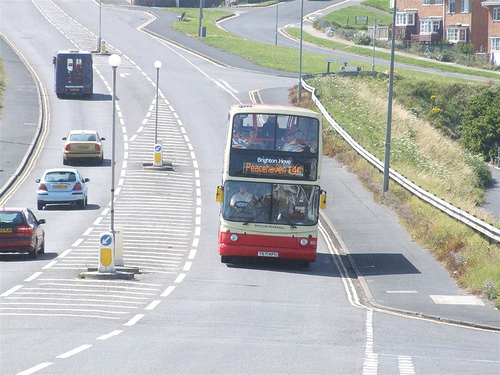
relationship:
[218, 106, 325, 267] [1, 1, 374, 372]
bus in road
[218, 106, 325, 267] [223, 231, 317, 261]
bus has bumper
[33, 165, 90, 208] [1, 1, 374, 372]
car on road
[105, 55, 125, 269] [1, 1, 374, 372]
pole in road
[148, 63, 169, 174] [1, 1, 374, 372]
pole in road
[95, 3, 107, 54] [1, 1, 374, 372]
pole in road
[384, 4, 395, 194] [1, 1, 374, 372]
pole in road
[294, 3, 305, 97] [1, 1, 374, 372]
pole in road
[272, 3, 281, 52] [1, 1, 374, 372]
pole in road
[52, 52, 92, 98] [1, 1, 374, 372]
truck in road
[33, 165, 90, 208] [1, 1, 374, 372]
car in road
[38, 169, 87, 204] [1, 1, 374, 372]
car on road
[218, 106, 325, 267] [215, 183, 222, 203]
bus has mirror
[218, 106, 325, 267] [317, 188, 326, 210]
bus has mirror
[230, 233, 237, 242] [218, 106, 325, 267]
light on bus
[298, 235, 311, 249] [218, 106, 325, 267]
headlight on bus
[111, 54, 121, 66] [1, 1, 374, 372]
light in road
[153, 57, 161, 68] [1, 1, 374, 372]
light in road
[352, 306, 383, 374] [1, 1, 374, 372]
line on road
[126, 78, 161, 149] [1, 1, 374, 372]
line on road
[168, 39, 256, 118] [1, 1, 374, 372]
line on road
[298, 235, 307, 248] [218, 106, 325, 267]
headlight of bus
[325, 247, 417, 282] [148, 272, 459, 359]
shadow cast in road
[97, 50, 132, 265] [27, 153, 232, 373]
pole on center of road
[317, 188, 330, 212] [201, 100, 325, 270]
mirror on bus